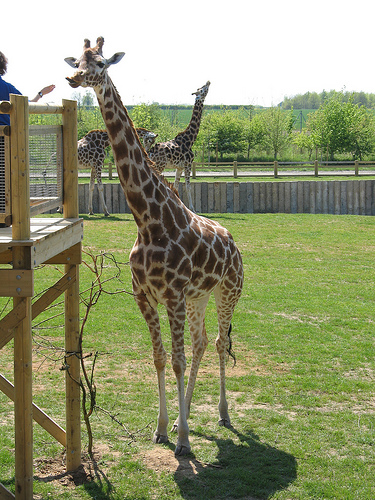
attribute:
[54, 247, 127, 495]
vine — dead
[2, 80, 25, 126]
shirt — blue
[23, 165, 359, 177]
fence — wood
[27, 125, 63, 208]
mesh — metal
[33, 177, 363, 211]
fence — wooden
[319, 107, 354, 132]
leaves — green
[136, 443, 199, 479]
spot — bare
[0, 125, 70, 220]
wall — wire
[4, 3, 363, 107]
sky — white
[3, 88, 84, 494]
platform — wooden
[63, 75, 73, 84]
tongue — small, black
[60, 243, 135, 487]
tree — tall, thin, leafless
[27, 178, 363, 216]
fence — wooden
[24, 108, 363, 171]
field — green